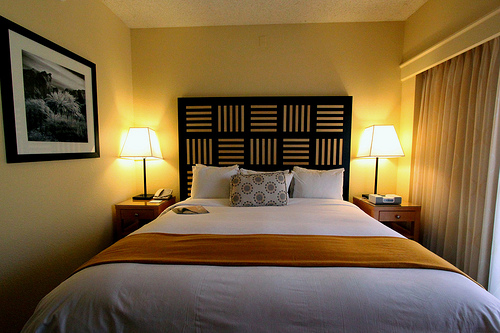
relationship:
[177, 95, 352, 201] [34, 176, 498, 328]
headboard for bed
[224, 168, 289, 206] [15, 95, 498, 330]
pillow on bed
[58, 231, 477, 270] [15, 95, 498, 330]
sheet on bed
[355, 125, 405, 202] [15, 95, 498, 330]
lampshade near bed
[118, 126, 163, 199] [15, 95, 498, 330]
lampshade near bed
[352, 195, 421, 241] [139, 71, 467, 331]
end table near bed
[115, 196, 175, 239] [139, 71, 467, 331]
end table near bed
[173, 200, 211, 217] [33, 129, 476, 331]
book lying on bed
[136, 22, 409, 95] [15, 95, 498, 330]
wall behind bed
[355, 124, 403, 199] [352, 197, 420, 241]
lamp on end table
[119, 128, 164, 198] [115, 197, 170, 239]
lamp on end table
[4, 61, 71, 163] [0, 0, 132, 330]
photograph on wall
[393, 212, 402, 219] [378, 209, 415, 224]
knob on drawer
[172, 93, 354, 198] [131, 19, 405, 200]
headboard against wall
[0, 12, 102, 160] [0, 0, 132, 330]
artwork on wall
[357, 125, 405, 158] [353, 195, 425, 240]
lamp on table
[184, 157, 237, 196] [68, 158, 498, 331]
pillow on bed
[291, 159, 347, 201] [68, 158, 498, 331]
pillow on bed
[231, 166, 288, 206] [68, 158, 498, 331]
pillow on bed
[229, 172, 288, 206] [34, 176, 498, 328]
pillow on bed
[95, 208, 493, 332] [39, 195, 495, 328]
bedsheets on bed